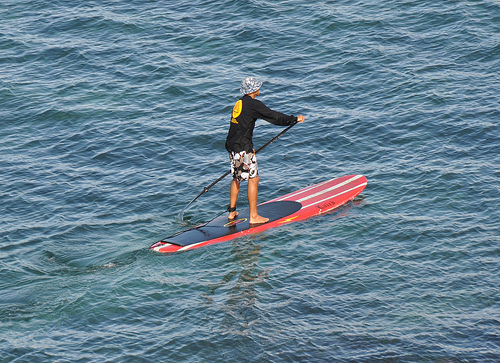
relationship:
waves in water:
[141, 47, 194, 102] [1, 1, 500, 363]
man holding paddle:
[225, 76, 304, 224] [180, 118, 301, 211]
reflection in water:
[201, 232, 273, 332] [1, 1, 500, 363]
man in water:
[225, 76, 304, 224] [1, 1, 500, 363]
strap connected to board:
[228, 207, 235, 212] [150, 175, 368, 254]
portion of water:
[384, 29, 446, 79] [1, 1, 500, 363]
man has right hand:
[225, 76, 304, 224] [298, 114, 306, 124]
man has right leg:
[225, 76, 304, 224] [247, 156, 259, 218]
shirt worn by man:
[225, 96, 297, 152] [225, 76, 304, 224]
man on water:
[225, 76, 304, 224] [1, 1, 500, 363]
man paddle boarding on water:
[225, 76, 304, 224] [1, 1, 500, 363]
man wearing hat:
[225, 76, 304, 224] [240, 76, 262, 95]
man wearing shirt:
[225, 76, 304, 224] [225, 96, 297, 152]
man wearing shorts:
[225, 76, 304, 224] [230, 150, 259, 180]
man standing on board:
[225, 76, 304, 224] [150, 175, 368, 254]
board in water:
[150, 175, 368, 254] [1, 1, 500, 363]